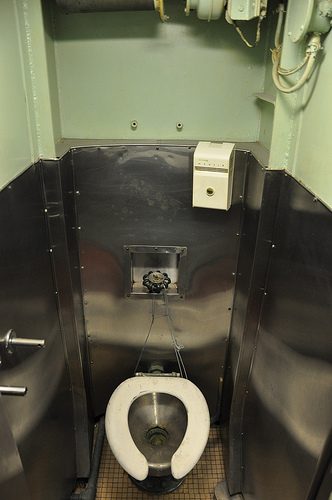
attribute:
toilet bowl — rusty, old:
[102, 365, 211, 494]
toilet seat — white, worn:
[103, 369, 210, 479]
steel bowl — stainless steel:
[129, 392, 187, 473]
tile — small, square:
[101, 466, 230, 496]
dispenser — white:
[172, 138, 268, 212]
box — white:
[192, 134, 235, 214]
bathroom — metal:
[1, 0, 331, 498]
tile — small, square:
[191, 465, 217, 495]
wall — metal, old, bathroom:
[76, 48, 177, 100]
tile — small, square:
[193, 492, 199, 497]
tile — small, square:
[111, 491, 118, 497]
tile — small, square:
[202, 477, 209, 483]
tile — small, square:
[108, 471, 115, 477]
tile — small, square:
[208, 453, 216, 460]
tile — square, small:
[180, 454, 230, 486]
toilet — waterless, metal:
[100, 369, 216, 495]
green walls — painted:
[1, 1, 331, 215]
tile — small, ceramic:
[72, 422, 228, 499]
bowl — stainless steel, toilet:
[103, 373, 209, 495]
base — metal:
[124, 473, 190, 499]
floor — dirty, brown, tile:
[70, 420, 223, 497]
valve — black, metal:
[141, 269, 171, 292]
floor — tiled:
[95, 425, 224, 496]